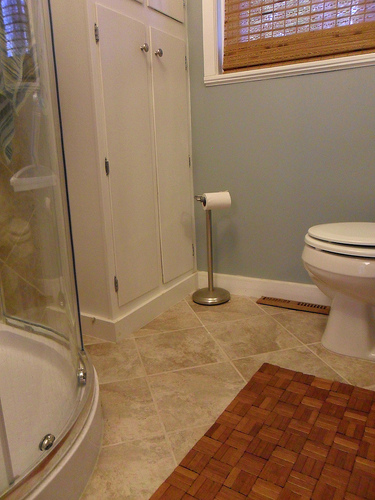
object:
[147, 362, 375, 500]
mat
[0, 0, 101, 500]
shower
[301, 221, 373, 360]
toilet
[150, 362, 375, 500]
wood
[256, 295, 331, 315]
floor vent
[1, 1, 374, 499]
bathroom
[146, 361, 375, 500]
piece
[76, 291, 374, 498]
floor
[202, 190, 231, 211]
tissue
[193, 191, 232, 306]
holder